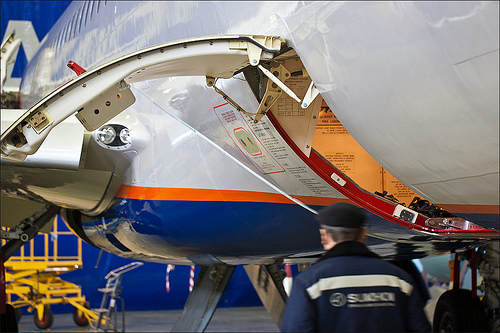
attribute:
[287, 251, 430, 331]
jacket — of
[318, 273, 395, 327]
back — of